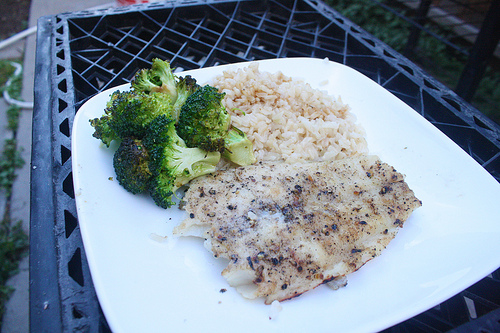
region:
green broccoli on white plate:
[101, 67, 219, 164]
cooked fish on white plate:
[216, 79, 402, 305]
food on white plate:
[87, 196, 114, 233]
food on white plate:
[138, 83, 315, 253]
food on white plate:
[214, 121, 321, 296]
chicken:
[287, 197, 364, 264]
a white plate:
[403, 235, 455, 275]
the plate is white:
[127, 250, 177, 291]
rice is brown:
[255, 95, 312, 138]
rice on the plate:
[240, 85, 308, 128]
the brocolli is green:
[101, 93, 208, 178]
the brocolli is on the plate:
[99, 90, 169, 185]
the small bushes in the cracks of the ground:
[6, 105, 23, 134]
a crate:
[117, 24, 217, 59]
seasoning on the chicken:
[270, 185, 352, 247]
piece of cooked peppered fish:
[174, 155, 429, 305]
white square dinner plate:
[71, 56, 498, 331]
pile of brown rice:
[205, 62, 372, 159]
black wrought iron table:
[27, 0, 499, 332]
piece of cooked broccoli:
[177, 82, 259, 165]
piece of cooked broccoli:
[112, 113, 220, 207]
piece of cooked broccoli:
[131, 58, 177, 125]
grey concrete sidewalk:
[0, 0, 122, 330]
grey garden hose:
[0, 21, 38, 111]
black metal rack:
[379, 0, 498, 105]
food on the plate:
[77, 33, 402, 298]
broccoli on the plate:
[91, 63, 216, 199]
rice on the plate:
[193, 48, 369, 174]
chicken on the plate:
[168, 155, 431, 282]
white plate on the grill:
[37, 28, 422, 330]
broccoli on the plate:
[68, 48, 275, 215]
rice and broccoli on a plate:
[101, 33, 361, 197]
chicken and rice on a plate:
[204, 59, 433, 289]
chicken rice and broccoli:
[106, 57, 416, 293]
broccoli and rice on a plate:
[78, 53, 258, 181]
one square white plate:
[67, 46, 497, 331]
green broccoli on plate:
[86, 48, 258, 206]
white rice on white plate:
[207, 65, 372, 170]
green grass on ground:
[325, 2, 498, 129]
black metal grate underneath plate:
[28, 1, 494, 328]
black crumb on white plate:
[214, 284, 229, 297]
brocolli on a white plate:
[96, 63, 236, 178]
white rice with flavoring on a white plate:
[215, 60, 351, 150]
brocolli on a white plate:
[90, 72, 190, 137]